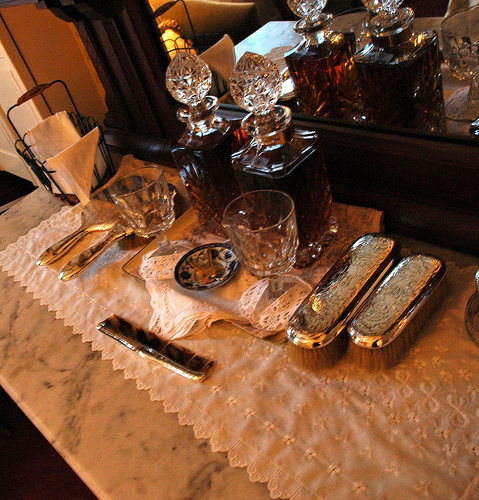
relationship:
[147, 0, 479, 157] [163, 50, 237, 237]
mirror behind bottle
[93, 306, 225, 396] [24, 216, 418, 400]
comb on white napkin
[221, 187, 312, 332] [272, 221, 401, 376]
cup next to brush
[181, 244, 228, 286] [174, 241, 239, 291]
keys in saucer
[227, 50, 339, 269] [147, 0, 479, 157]
bottle against mirror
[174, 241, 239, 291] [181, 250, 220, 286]
saucer has keys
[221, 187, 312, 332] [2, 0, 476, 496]
cup on dresser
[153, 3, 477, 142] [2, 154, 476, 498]
mirror on dresser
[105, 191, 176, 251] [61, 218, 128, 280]
brush with handle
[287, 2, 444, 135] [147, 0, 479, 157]
bottle reflection in mirror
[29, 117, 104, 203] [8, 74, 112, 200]
cloth in basket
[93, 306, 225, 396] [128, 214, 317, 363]
comb on front napkin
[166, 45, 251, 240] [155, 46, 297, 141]
bottles with toppers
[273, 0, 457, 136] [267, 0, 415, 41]
bottles with toppers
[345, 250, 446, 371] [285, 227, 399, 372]
brush next to brush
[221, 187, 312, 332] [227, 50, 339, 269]
cup in front of bottle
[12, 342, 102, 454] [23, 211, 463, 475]
top on dresser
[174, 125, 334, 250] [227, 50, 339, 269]
alcohol in bottle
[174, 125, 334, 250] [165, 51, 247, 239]
alcohol in bottle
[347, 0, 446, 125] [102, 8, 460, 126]
bottle in mirror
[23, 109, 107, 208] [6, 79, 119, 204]
napkin on basket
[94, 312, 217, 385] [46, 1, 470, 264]
comb on dresser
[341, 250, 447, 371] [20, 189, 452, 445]
brush on dresser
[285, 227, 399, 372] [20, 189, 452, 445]
brush on dresser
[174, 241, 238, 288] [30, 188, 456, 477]
saucer on dresser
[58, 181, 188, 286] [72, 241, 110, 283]
brush with handle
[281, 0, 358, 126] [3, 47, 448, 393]
bottle reflection of items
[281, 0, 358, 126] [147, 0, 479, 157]
bottle reflection in mirror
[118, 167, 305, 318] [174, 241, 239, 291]
glasses with saucer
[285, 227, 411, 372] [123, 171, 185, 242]
brush by glass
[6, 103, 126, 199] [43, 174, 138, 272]
basket next to brushes